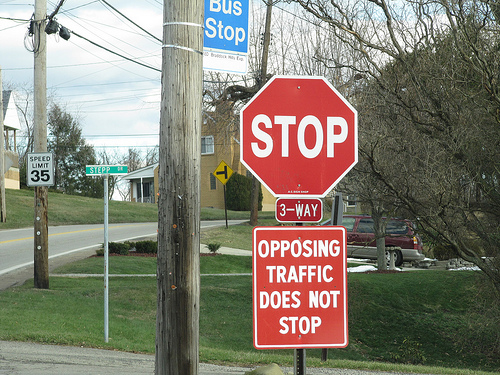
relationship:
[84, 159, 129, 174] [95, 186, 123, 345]
sign on post